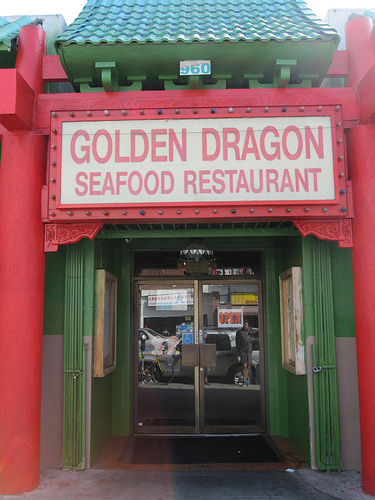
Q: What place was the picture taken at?
A: It was taken at the restaurant.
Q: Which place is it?
A: It is a restaurant.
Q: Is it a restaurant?
A: Yes, it is a restaurant.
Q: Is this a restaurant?
A: Yes, it is a restaurant.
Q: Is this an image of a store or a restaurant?
A: It is showing a restaurant.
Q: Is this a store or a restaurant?
A: It is a restaurant.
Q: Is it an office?
A: No, it is a restaurant.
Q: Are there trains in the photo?
A: No, there are no trains.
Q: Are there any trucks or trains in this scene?
A: No, there are no trains or trucks.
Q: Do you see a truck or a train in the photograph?
A: No, there are no trains or trucks.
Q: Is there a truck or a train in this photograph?
A: No, there are no trains or trucks.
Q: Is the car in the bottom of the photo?
A: Yes, the car is in the bottom of the image.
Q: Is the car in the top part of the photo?
A: No, the car is in the bottom of the image.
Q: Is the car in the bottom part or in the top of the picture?
A: The car is in the bottom of the image.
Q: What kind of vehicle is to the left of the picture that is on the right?
A: The vehicle is a car.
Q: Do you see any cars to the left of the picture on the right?
A: Yes, there is a car to the left of the picture.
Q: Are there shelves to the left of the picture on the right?
A: No, there is a car to the left of the picture.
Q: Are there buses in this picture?
A: No, there are no buses.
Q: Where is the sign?
A: The sign is on the restaurant.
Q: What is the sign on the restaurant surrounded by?
A: The sign is surrounded by the light bulbs.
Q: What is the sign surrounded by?
A: The sign is surrounded by the light bulbs.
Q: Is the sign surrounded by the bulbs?
A: Yes, the sign is surrounded by the bulbs.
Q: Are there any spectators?
A: No, there are no spectators.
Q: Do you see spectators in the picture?
A: No, there are no spectators.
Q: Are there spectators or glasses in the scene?
A: No, there are no spectators or glasses.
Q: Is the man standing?
A: Yes, the man is standing.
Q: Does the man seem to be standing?
A: Yes, the man is standing.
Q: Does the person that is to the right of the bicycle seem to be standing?
A: Yes, the man is standing.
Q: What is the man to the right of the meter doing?
A: The man is standing.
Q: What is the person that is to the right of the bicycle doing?
A: The man is standing.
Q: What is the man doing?
A: The man is standing.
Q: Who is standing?
A: The man is standing.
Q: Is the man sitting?
A: No, the man is standing.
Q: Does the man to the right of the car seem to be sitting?
A: No, the man is standing.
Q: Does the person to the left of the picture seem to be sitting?
A: No, the man is standing.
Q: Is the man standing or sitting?
A: The man is standing.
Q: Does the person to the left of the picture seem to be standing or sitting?
A: The man is standing.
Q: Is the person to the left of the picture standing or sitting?
A: The man is standing.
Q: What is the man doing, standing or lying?
A: The man is standing.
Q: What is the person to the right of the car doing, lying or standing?
A: The man is standing.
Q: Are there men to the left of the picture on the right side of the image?
A: Yes, there is a man to the left of the picture.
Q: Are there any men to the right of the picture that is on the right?
A: No, the man is to the left of the picture.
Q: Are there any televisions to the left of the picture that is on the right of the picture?
A: No, there is a man to the left of the picture.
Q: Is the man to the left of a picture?
A: Yes, the man is to the left of a picture.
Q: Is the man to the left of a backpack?
A: No, the man is to the left of a picture.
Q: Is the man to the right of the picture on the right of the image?
A: No, the man is to the left of the picture.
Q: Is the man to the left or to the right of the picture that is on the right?
A: The man is to the left of the picture.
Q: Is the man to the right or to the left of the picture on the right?
A: The man is to the left of the picture.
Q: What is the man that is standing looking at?
A: The man is looking at the restaurant.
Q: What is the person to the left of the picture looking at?
A: The man is looking at the restaurant.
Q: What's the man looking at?
A: The man is looking at the restaurant.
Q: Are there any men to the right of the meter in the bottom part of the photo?
A: Yes, there is a man to the right of the parking meter.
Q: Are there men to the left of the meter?
A: No, the man is to the right of the meter.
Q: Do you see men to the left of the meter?
A: No, the man is to the right of the meter.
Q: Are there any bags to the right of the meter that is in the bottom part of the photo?
A: No, there is a man to the right of the meter.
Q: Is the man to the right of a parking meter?
A: Yes, the man is to the right of a parking meter.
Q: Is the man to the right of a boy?
A: No, the man is to the right of a parking meter.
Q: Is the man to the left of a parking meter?
A: No, the man is to the right of a parking meter.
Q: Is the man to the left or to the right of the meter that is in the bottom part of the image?
A: The man is to the right of the parking meter.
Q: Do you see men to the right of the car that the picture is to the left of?
A: Yes, there is a man to the right of the car.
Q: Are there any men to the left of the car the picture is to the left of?
A: No, the man is to the right of the car.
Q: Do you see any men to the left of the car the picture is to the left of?
A: No, the man is to the right of the car.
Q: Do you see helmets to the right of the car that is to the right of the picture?
A: No, there is a man to the right of the car.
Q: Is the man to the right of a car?
A: Yes, the man is to the right of a car.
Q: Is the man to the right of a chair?
A: No, the man is to the right of a car.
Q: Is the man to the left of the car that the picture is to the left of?
A: No, the man is to the right of the car.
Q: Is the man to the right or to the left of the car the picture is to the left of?
A: The man is to the right of the car.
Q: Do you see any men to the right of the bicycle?
A: Yes, there is a man to the right of the bicycle.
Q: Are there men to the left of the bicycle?
A: No, the man is to the right of the bicycle.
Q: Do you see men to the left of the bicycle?
A: No, the man is to the right of the bicycle.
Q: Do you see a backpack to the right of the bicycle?
A: No, there is a man to the right of the bicycle.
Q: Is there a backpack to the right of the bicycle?
A: No, there is a man to the right of the bicycle.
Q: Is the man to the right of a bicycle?
A: Yes, the man is to the right of a bicycle.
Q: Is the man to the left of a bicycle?
A: No, the man is to the right of a bicycle.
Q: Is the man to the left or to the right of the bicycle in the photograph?
A: The man is to the right of the bicycle.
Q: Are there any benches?
A: No, there are no benches.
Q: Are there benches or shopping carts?
A: No, there are no benches or shopping carts.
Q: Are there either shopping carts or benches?
A: No, there are no benches or shopping carts.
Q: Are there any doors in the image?
A: Yes, there are doors.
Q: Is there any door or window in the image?
A: Yes, there are doors.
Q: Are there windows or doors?
A: Yes, there are doors.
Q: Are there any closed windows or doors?
A: Yes, there are closed doors.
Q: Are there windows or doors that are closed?
A: Yes, the doors are closed.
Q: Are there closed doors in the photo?
A: Yes, there are closed doors.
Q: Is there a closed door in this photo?
A: Yes, there are closed doors.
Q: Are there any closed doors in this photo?
A: Yes, there are closed doors.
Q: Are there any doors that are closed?
A: Yes, there are doors that are closed.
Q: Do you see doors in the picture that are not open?
A: Yes, there are closed doors.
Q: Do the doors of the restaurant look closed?
A: Yes, the doors are closed.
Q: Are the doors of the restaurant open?
A: No, the doors are closed.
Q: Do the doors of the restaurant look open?
A: No, the doors are closed.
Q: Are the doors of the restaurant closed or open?
A: The doors are closed.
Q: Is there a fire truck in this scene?
A: No, there are no fire trucks.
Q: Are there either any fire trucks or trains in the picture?
A: No, there are no fire trucks or trains.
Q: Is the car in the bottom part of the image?
A: Yes, the car is in the bottom of the image.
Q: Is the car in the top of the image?
A: No, the car is in the bottom of the image.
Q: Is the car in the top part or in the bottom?
A: The car is in the bottom of the image.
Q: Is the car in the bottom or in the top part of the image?
A: The car is in the bottom of the image.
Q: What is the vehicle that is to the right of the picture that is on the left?
A: The vehicle is a car.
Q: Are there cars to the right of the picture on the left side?
A: Yes, there is a car to the right of the picture.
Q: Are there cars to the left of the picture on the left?
A: No, the car is to the right of the picture.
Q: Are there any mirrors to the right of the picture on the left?
A: No, there is a car to the right of the picture.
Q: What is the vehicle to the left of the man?
A: The vehicle is a car.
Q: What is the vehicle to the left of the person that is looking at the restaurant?
A: The vehicle is a car.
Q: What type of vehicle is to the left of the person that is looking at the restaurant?
A: The vehicle is a car.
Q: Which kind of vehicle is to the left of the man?
A: The vehicle is a car.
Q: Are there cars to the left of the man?
A: Yes, there is a car to the left of the man.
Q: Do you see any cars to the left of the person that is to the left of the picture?
A: Yes, there is a car to the left of the man.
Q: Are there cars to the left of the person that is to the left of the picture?
A: Yes, there is a car to the left of the man.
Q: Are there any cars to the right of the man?
A: No, the car is to the left of the man.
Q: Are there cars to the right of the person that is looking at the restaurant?
A: No, the car is to the left of the man.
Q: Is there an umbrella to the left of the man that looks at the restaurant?
A: No, there is a car to the left of the man.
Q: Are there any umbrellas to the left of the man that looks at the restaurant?
A: No, there is a car to the left of the man.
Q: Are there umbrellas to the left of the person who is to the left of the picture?
A: No, there is a car to the left of the man.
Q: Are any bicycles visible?
A: Yes, there is a bicycle.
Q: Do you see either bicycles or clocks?
A: Yes, there is a bicycle.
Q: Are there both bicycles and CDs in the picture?
A: No, there is a bicycle but no cds.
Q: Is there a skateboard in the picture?
A: No, there are no skateboards.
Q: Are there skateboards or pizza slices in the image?
A: No, there are no skateboards or pizza slices.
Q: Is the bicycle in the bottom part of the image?
A: Yes, the bicycle is in the bottom of the image.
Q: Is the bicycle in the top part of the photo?
A: No, the bicycle is in the bottom of the image.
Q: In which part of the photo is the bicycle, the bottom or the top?
A: The bicycle is in the bottom of the image.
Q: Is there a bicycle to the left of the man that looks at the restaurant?
A: Yes, there is a bicycle to the left of the man.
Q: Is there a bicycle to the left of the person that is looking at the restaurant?
A: Yes, there is a bicycle to the left of the man.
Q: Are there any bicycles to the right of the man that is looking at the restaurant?
A: No, the bicycle is to the left of the man.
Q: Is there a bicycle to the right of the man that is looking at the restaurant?
A: No, the bicycle is to the left of the man.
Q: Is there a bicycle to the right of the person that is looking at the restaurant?
A: No, the bicycle is to the left of the man.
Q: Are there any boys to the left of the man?
A: No, there is a bicycle to the left of the man.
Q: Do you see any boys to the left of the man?
A: No, there is a bicycle to the left of the man.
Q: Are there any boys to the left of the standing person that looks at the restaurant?
A: No, there is a bicycle to the left of the man.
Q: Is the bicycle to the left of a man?
A: Yes, the bicycle is to the left of a man.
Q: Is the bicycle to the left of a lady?
A: No, the bicycle is to the left of a man.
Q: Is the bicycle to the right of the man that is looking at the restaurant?
A: No, the bicycle is to the left of the man.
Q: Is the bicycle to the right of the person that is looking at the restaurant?
A: No, the bicycle is to the left of the man.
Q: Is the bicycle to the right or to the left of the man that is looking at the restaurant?
A: The bicycle is to the left of the man.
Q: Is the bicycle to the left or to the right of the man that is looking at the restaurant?
A: The bicycle is to the left of the man.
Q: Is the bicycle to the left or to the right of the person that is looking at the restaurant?
A: The bicycle is to the left of the man.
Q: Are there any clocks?
A: No, there are no clocks.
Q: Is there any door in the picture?
A: Yes, there is a door.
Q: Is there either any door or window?
A: Yes, there is a door.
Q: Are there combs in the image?
A: No, there are no combs.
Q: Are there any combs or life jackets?
A: No, there are no combs or life jackets.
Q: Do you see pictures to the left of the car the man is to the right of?
A: Yes, there is a picture to the left of the car.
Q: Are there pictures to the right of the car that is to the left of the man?
A: No, the picture is to the left of the car.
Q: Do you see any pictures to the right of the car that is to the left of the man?
A: No, the picture is to the left of the car.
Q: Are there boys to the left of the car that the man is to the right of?
A: No, there is a picture to the left of the car.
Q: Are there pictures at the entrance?
A: Yes, there is a picture at the entrance.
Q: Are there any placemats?
A: No, there are no placemats.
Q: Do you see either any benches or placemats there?
A: No, there are no placemats or benches.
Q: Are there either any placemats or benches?
A: No, there are no placemats or benches.